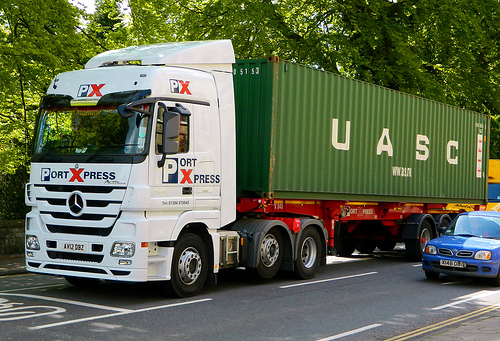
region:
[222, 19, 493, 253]
green trailer on truck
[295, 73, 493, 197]
white letters on green conatiner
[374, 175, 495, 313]
blue car driving on road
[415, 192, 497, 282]
blue car next to trailer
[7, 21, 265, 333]
white front of trailer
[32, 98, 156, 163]
window of trailer truck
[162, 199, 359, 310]
wheels on trailer truck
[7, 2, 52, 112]
green leafy tree branch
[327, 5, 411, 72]
green leafy tree branch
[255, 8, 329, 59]
green leafy tree branch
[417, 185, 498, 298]
blue car next to truck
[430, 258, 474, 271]
license plate on the car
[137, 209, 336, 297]
three wheels in front of truck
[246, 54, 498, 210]
truck cargo is green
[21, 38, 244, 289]
cab of the truck is white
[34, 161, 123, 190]
Port Xpress is written on the front of truck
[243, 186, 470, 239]
bed of truck is red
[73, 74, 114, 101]
PX is on the top of the truck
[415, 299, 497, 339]
double yellow line in the road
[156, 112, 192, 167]
sidemirror on the truck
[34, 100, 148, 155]
A windshield on a truck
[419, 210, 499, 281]
A blue car on the street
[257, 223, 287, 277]
A tire on a truck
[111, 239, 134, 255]
A single headlight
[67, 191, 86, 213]
A Mercedes logo on a truck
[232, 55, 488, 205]
A green trailer on a truck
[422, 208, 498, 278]
A small blue car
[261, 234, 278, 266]
The wheel of a tire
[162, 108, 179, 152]
A mirror on a truck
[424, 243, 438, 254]
A headlight on a blue car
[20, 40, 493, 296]
truck with white cab and green and red trailer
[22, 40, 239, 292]
white truck cab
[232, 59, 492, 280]
green and red tractor trailer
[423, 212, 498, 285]
blue car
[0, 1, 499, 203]
stand of tall trees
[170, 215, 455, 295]
truck tires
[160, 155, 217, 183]
company logo Port Xpress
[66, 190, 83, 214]
black and silver mercedes logo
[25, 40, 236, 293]
white Mercedes truck cab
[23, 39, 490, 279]
white Mercedes truck cab hauling green container on red tractor trailer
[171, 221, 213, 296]
black wheel on truck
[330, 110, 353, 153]
white U lettering on trailer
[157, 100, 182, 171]
side mirror on truck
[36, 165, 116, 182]
port xperss decal for truck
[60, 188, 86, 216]
mercedes emblem on truck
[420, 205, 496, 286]
blue sabb on road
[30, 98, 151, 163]
wind shield for semi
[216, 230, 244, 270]
step latter for truck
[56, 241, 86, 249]
eupopean licence plate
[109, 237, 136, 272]
head lamps for truck